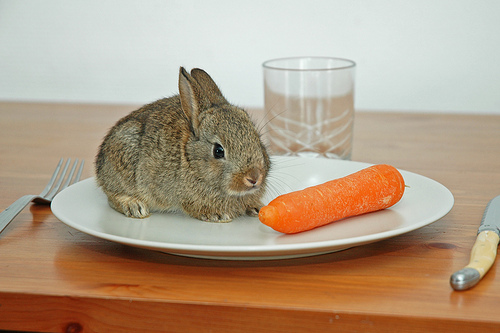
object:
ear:
[177, 66, 213, 136]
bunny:
[92, 65, 273, 223]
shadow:
[95, 200, 406, 247]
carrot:
[257, 163, 411, 234]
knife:
[448, 194, 499, 292]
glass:
[261, 55, 356, 161]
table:
[0, 99, 500, 333]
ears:
[189, 67, 229, 106]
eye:
[212, 141, 225, 159]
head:
[177, 65, 269, 196]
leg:
[107, 189, 150, 219]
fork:
[0, 157, 85, 233]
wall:
[0, 0, 500, 116]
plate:
[50, 155, 455, 261]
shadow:
[53, 211, 455, 268]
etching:
[263, 105, 353, 160]